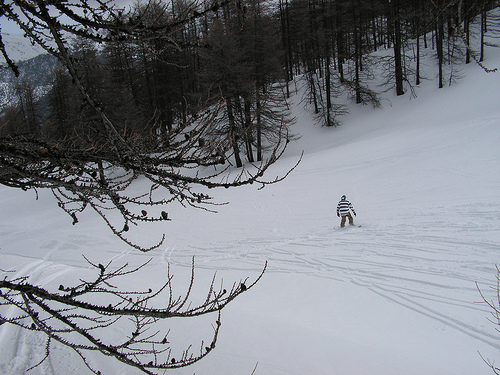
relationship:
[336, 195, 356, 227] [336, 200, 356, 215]
man wearing shirt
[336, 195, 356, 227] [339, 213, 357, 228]
man wearing pants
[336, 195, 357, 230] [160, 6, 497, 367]
man traveling on hill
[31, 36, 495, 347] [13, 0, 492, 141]
snow covering hill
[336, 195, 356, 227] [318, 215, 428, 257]
man on top of snowboard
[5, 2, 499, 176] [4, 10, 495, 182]
trees are on top of hill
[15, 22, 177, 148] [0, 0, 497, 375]
snow on top of hill